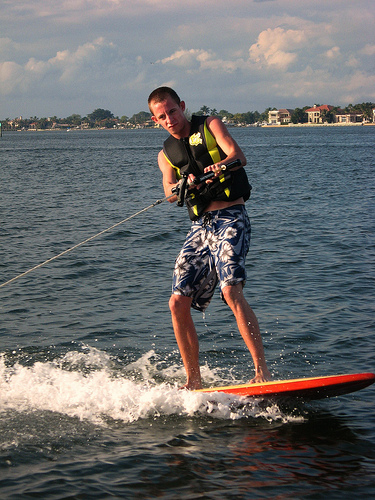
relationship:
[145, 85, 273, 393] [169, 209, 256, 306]
boy wearing shorts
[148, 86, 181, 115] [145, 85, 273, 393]
hair of boy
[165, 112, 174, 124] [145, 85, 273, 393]
nose of boy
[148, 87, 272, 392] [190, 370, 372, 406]
boy on board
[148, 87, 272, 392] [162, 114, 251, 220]
boy wearing a vest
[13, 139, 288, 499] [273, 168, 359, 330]
waves in water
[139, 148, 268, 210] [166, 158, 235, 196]
hands gripping handlebars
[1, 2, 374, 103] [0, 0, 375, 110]
sky filled with cloud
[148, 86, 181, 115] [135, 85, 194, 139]
hair on head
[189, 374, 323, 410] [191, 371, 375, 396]
part of a board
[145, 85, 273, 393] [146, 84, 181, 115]
boy has hair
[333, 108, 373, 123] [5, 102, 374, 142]
building on shore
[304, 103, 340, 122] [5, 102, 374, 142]
building on shore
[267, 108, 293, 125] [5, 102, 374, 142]
building on shore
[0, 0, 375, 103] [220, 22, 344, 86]
sky has clouds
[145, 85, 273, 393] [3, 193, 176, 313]
boy holds cord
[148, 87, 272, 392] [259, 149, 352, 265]
boy on water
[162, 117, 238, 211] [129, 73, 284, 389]
vest on man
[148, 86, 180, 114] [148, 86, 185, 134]
hair on head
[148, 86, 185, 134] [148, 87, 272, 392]
head on boy